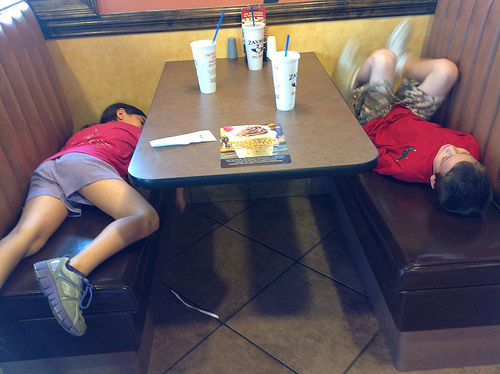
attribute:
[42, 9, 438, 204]
wall — yellow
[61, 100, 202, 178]
shirt — red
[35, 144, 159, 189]
shorts — gray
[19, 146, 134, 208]
shorts — purple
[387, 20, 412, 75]
shoes — white 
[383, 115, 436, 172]
red shirt — bright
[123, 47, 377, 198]
table — fast food, restaurant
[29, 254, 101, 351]
shoe — purple, gray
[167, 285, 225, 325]
paper — white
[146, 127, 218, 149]
napkin — white 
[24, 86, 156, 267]
child — exhausted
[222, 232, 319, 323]
floor — restaurant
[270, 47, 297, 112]
cup — white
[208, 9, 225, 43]
straw — blue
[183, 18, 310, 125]
cups — three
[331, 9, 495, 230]
boy — young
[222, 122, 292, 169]
advertisement — restaurant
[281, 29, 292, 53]
straw — blue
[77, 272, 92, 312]
laces — long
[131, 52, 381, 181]
table — BROWN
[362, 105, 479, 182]
shirt — red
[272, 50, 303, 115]
cup — zaxbys, drink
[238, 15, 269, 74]
cup — zaxbys, drink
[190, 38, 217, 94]
cup — zaxbys, drink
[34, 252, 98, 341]
sneaker — gray, silver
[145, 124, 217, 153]
bill — white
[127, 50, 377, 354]
table — brown